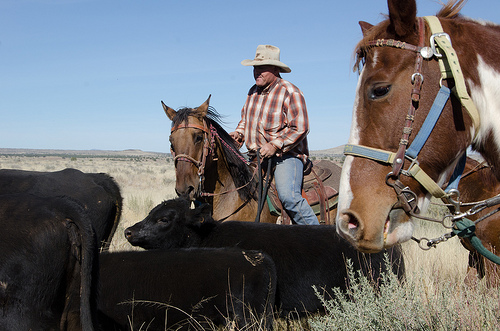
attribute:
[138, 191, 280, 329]
cows — baby, black, walking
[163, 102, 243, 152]
mane — black 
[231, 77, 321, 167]
shirt — plaid shirt 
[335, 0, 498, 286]
horse — brown, white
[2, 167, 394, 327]
cattle — black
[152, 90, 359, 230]
horse — brown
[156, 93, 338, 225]
horse — Brown 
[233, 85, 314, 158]
shirt — checkered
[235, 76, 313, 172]
shirt — plaid , button down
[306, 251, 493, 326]
weeds — Tall, green 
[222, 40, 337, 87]
hat — white, cowboy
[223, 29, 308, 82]
hat — Khaki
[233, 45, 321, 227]
man — Riding 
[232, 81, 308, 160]
shirt — plaid